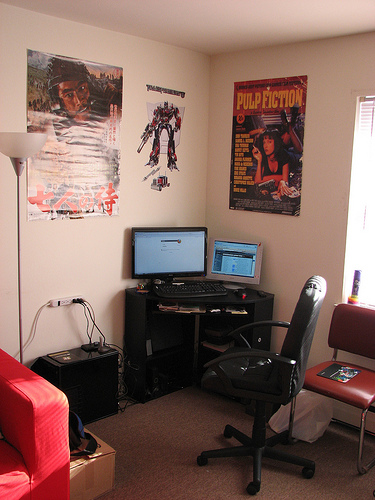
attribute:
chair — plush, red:
[3, 347, 75, 497]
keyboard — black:
[152, 270, 230, 300]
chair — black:
[195, 273, 328, 496]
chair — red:
[315, 357, 368, 395]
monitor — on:
[125, 223, 210, 292]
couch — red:
[6, 327, 117, 498]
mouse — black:
[242, 292, 246, 298]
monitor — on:
[127, 225, 210, 276]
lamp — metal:
[1, 131, 47, 365]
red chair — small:
[289, 304, 374, 473]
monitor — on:
[148, 223, 212, 273]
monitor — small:
[208, 233, 270, 292]